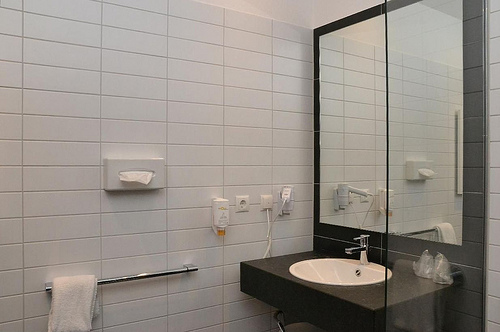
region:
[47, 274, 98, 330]
White towel hanging on a rack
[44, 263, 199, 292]
Metallic towel rack affixed to the wall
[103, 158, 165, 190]
White tissue box attached to the wall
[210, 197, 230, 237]
Soap despenser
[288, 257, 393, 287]
White porcelain sink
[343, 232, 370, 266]
Metallic water faucet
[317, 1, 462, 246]
Bathroom mirror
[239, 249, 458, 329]
Black bathroom counter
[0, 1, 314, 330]
White tile bathroom wall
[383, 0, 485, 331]
Glass wall in a bathroom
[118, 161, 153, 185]
White napking hanging from the wall.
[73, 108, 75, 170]
White napking hanging from the wall.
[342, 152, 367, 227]
White napking hanging from the wall.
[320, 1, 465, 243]
it is a mirror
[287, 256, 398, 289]
it is a wash passon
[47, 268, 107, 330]
it is white color towel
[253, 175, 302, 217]
it is a plug point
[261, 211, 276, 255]
it is an cable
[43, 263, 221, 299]
it is a towel hanger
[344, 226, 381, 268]
it is a tap in wash passion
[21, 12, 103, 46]
white tile on wall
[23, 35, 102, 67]
white tile on wall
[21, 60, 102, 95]
white tile on wall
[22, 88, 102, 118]
white tile on wall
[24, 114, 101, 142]
white tile on wall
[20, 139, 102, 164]
white tile on wall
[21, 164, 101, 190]
white tile on wall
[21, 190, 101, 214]
white tile on wall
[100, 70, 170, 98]
white tile on wall